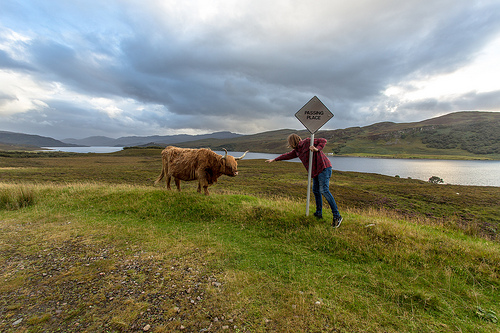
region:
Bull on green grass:
[148, 133, 253, 198]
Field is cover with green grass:
[1, 155, 493, 330]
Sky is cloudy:
[1, 2, 498, 135]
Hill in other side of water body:
[136, 102, 498, 152]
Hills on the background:
[4, 128, 185, 145]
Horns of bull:
[219, 145, 250, 162]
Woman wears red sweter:
[259, 128, 356, 237]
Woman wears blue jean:
[261, 120, 358, 250]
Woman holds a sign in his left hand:
[262, 80, 354, 238]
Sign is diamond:
[288, 86, 335, 143]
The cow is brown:
[155, 124, 267, 199]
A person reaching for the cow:
[271, 91, 353, 258]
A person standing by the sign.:
[279, 86, 357, 253]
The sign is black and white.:
[280, 82, 329, 223]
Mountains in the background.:
[25, 72, 292, 159]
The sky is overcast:
[158, 21, 425, 96]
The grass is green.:
[38, 202, 363, 309]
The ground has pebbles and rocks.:
[51, 245, 197, 315]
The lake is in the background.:
[381, 153, 493, 205]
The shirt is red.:
[288, 138, 351, 174]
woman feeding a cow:
[137, 95, 357, 234]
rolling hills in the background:
[434, 105, 494, 136]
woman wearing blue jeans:
[286, 129, 343, 227]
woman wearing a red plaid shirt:
[276, 132, 357, 232]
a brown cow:
[156, 137, 246, 201]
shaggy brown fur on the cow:
[169, 149, 186, 169]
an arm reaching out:
[260, 145, 291, 165]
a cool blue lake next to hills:
[386, 152, 438, 176]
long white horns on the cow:
[221, 142, 254, 161]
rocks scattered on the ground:
[119, 271, 201, 323]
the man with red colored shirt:
[265, 129, 365, 231]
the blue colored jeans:
[302, 168, 366, 231]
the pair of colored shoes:
[312, 208, 351, 235]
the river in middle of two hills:
[380, 156, 484, 184]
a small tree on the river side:
[425, 173, 445, 190]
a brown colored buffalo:
[145, 132, 255, 212]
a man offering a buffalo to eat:
[145, 123, 365, 229]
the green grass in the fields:
[223, 207, 374, 304]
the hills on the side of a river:
[370, 107, 485, 162]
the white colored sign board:
[289, 86, 336, 232]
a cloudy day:
[19, 7, 489, 332]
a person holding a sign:
[269, 93, 371, 233]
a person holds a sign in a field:
[271, 88, 368, 242]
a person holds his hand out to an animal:
[149, 68, 376, 225]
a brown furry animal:
[153, 141, 261, 198]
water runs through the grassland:
[29, 129, 492, 201]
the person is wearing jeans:
[272, 131, 358, 228]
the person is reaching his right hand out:
[267, 128, 389, 237]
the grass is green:
[72, 174, 465, 322]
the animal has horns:
[153, 138, 250, 198]